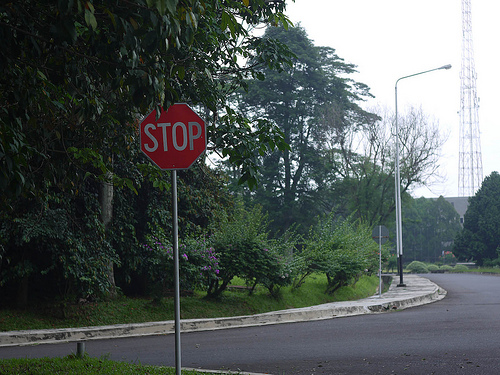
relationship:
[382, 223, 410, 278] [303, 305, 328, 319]
lamp posts are on sidewalk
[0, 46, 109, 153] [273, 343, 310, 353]
trees on side of road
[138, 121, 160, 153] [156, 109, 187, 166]
s on sign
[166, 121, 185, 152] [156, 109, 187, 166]
o on sign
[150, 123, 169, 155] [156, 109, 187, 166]
t on sign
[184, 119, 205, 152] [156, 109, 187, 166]
p on sign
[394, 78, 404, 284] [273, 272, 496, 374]
lamp posts next to road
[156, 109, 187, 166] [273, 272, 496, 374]
sign on road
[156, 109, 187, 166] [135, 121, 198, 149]
sign says stop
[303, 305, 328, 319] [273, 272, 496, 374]
sidewalk lines road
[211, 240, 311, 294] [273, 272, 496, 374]
bushes line road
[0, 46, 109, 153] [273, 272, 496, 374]
trees line road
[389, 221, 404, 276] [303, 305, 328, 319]
light on sidewalk